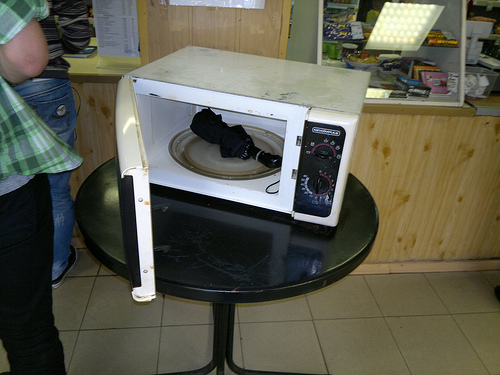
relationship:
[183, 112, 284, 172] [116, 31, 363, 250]
umbrella in microwave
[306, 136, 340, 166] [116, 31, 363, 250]
dial on microwave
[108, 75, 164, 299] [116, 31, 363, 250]
door for microwave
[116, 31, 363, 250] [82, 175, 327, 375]
microwave on top of table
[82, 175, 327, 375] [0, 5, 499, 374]
table in room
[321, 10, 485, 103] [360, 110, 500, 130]
display on top of counter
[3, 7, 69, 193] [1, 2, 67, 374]
shirt on person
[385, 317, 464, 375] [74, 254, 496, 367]
tile on floor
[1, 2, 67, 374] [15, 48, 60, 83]
person has elbow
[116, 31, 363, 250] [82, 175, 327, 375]
microwave on table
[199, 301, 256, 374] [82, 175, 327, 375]
base of table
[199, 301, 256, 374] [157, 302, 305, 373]
base in underneath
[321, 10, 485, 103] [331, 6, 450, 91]
cabinet has food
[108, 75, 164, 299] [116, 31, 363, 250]
door of microwave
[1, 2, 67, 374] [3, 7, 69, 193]
person has shirt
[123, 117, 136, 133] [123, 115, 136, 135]
light of light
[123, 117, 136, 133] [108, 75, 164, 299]
light on door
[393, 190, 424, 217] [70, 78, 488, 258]
knot in wood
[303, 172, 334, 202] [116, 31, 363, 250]
dial on microwave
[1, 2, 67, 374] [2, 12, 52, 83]
person has arm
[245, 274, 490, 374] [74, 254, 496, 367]
section of floor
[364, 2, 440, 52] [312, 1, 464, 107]
lights on glass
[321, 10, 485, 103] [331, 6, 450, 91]
display for snacks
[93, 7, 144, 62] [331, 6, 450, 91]
menu for snacks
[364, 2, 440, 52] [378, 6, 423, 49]
lights of lights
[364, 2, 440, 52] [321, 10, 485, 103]
lights on display case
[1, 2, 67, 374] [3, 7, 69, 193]
person in shirt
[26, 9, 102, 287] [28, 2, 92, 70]
person in shirt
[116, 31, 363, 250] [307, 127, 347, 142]
microwave has branding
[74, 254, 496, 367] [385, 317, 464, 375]
floor has tile